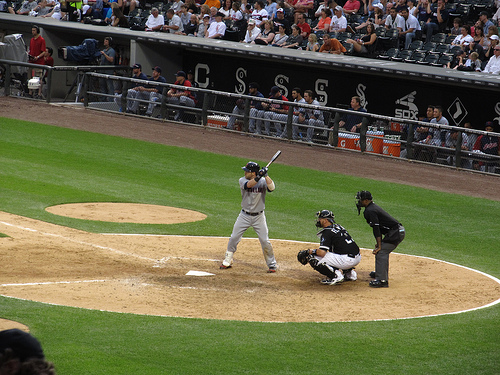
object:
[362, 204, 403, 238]
shirt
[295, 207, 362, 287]
catcher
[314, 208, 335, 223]
helmet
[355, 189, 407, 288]
umpire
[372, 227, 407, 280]
pants